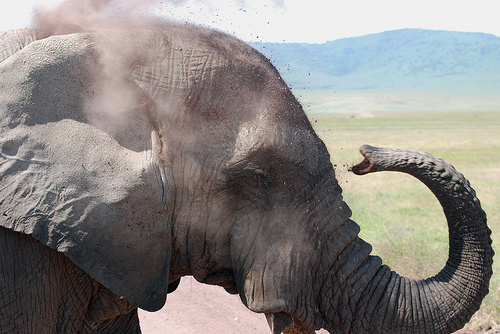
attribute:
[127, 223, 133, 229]
mark — black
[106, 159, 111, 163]
mark — black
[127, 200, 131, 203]
mark — black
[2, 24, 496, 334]
elephant — very old, african, gray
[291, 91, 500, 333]
field — green grass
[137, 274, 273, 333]
road — dirt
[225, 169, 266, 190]
right eye — open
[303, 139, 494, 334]
trunk — curled, ridged, opened, lifted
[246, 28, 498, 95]
mountain — distant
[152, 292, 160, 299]
spot — white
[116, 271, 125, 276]
spot — white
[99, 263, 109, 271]
spot — white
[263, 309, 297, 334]
tush — stub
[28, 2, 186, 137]
dust — dirt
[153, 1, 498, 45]
sky — cloudless